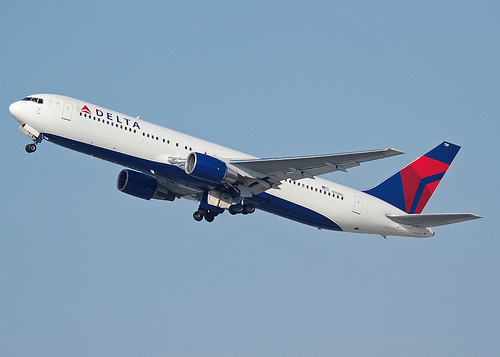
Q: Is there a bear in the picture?
A: No, there are no bears.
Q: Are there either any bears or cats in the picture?
A: No, there are no bears or cats.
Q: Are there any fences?
A: No, there are no fences.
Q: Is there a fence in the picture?
A: No, there are no fences.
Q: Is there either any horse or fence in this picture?
A: No, there are no fences or horses.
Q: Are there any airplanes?
A: Yes, there is an airplane.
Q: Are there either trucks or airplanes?
A: Yes, there is an airplane.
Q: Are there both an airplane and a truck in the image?
A: No, there is an airplane but no trucks.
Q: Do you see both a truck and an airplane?
A: No, there is an airplane but no trucks.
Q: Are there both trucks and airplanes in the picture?
A: No, there is an airplane but no trucks.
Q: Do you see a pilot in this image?
A: No, there are no pilots.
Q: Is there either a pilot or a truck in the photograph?
A: No, there are no pilots or trucks.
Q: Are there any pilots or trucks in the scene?
A: No, there are no pilots or trucks.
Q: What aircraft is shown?
A: The aircraft is an airplane.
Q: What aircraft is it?
A: The aircraft is an airplane.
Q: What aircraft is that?
A: This is an airplane.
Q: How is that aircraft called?
A: This is an airplane.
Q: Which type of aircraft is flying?
A: The aircraft is an airplane.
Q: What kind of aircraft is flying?
A: The aircraft is an airplane.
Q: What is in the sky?
A: The plane is in the sky.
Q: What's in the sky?
A: The plane is in the sky.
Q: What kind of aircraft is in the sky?
A: The aircraft is an airplane.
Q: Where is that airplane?
A: The airplane is in the sky.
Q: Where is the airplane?
A: The airplane is in the sky.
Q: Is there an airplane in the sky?
A: Yes, there is an airplane in the sky.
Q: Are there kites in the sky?
A: No, there is an airplane in the sky.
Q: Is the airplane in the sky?
A: Yes, the airplane is in the sky.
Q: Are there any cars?
A: No, there are no cars.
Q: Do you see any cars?
A: No, there are no cars.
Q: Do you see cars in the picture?
A: No, there are no cars.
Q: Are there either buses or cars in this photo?
A: No, there are no cars or buses.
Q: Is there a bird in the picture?
A: No, there are no birds.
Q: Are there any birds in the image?
A: No, there are no birds.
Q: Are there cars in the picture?
A: No, there are no cars.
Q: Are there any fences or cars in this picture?
A: No, there are no cars or fences.